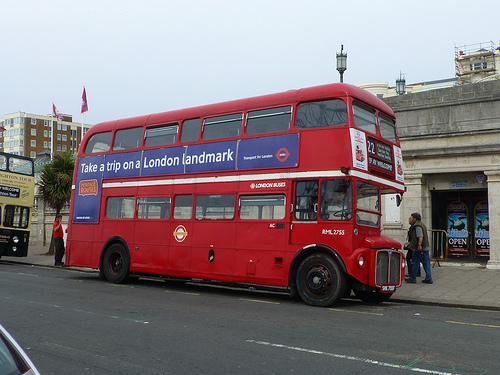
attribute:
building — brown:
[6, 110, 111, 195]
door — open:
[431, 190, 491, 266]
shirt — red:
[47, 81, 404, 304]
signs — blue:
[422, 169, 485, 275]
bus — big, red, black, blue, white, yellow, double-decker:
[61, 82, 410, 309]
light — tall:
[331, 42, 351, 83]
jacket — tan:
[406, 220, 431, 249]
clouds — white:
[362, 7, 422, 63]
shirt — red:
[44, 197, 70, 249]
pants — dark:
[47, 231, 68, 268]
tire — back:
[102, 235, 131, 279]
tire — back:
[156, 276, 184, 288]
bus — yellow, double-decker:
[56, 77, 448, 306]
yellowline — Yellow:
[433, 312, 498, 334]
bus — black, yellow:
[8, 155, 32, 257]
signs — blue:
[445, 206, 498, 259]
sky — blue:
[9, 11, 498, 147]